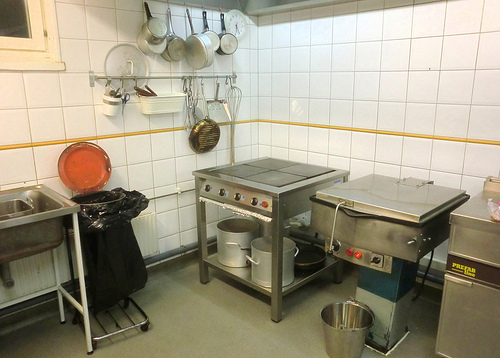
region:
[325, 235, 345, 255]
Small black knob on applience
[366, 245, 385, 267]
Small black knob on applience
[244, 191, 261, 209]
Small black knob on applience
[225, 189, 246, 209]
Small black knob on applience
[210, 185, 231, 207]
Small black knob on applience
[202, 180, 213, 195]
Small black knob on applience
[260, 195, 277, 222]
Small red knob on applience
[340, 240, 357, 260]
Small red knob on applience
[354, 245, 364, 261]
Small red knob on applience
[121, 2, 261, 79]
Pots hanging on the wall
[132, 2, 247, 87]
Pams handging on wall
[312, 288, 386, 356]
Pail on the flooe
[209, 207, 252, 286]
Silver pots on shelf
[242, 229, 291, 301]
Silver pots on shelf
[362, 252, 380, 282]
Black knob on applience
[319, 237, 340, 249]
Black knob on applience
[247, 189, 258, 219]
Black knob on applience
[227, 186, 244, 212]
Black knob on applience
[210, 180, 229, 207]
Black knob on applience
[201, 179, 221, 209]
Black knob on applience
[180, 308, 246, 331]
gray color on the floor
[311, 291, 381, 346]
shiny silver bucket on floor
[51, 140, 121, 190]
large round orange plate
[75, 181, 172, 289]
large black trash can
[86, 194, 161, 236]
shiny black trash bag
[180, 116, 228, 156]
silver skillet on wall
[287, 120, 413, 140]
orange line on the white wall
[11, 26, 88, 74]
white edge of the window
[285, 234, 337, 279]
black skillet under stove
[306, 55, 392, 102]
white tiles on the wall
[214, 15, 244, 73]
Pot hanging against wall.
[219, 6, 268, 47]
White clock attached to wall.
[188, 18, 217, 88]
Large pan hanging off wall.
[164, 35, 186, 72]
Silver pan hanging from wall.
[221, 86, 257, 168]
Large silver whisk hanging on wall.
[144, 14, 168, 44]
Silver pot has black handle.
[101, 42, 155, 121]
Lid to pot on rack against wall.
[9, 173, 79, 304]
Silver sink near wall.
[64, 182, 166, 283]
Black garbage bag on holder.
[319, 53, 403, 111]
White square tiles on wall.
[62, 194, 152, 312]
a black garbage bin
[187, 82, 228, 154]
a frying pan hanged on the wall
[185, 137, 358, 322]
an electronic powered stove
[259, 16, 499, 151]
the kitchen tiles on the wall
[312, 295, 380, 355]
an empty bin on the floor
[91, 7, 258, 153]
kitchen wares hanged on the wall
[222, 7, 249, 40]
a white clock on the wall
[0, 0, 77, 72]
a window on wall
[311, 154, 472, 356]
a type of kitchen machinary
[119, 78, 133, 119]
a scissor hanged on the wall